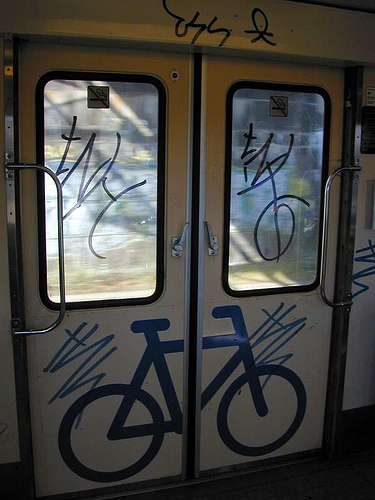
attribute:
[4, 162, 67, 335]
doorhandlebar — silver, metal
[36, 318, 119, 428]
graffitti — blue 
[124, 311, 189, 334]
seat — small, padded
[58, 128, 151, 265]
graffiti — blue, ugly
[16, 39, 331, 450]
door — closed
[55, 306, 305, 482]
graphic — blue 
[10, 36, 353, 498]
door — double, closed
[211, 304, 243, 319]
handle bar —  small, short, blue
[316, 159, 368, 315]
handle — metal, silver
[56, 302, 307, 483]
clipart — blue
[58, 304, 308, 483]
symbol — black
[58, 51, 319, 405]
doors — white 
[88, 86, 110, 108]
sticker — non smoking stickers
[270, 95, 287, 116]
sticker — non smoking stickers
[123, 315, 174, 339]
seat — blue, small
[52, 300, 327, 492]
bicycle — painted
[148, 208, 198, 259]
handle — silver 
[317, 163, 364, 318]
handle — metal, silver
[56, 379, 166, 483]
wheel — round, blue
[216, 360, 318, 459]
wheel — blue, round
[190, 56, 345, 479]
door — closed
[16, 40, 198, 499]
door — tall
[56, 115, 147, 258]
doodles — black, ugly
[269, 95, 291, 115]
sticker — non smoking stickers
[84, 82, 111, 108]
sticker — non smoking stickers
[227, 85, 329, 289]
window — narrow, marked, clear, long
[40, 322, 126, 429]
blue graffiti — ugly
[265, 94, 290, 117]
label — no smoking label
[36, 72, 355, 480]
door — double, closed, narrow, metal